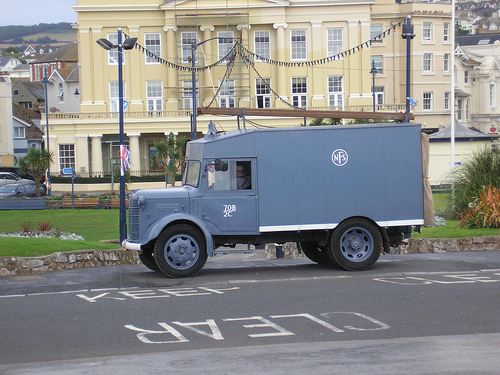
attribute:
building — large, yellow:
[39, 6, 498, 197]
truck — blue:
[144, 121, 434, 321]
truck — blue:
[140, 185, 419, 217]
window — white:
[140, 76, 170, 116]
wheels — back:
[299, 217, 382, 273]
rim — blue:
[166, 235, 198, 270]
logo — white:
[331, 148, 347, 165]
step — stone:
[399, 234, 495, 254]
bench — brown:
[48, 195, 136, 207]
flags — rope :
[135, 23, 405, 69]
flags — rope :
[133, 33, 398, 69]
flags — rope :
[137, 22, 409, 84]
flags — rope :
[114, 23, 406, 79]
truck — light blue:
[121, 122, 435, 280]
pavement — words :
[57, 251, 481, 345]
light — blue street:
[81, 27, 147, 66]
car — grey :
[0, 177, 39, 197]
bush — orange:
[452, 177, 484, 216]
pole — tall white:
[444, 5, 463, 208]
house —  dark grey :
[5, 64, 90, 170]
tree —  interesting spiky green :
[449, 150, 484, 234]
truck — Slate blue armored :
[114, 122, 428, 294]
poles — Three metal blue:
[98, 30, 422, 248]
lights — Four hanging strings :
[127, 21, 412, 109]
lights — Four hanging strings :
[128, 26, 392, 105]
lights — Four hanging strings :
[128, 21, 397, 100]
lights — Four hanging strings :
[137, 23, 402, 107]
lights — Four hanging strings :
[137, 21, 423, 113]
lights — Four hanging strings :
[116, 12, 416, 113]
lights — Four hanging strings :
[134, 29, 415, 101]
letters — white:
[328, 145, 351, 166]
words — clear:
[66, 273, 393, 353]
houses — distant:
[2, 33, 78, 193]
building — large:
[32, 4, 381, 187]